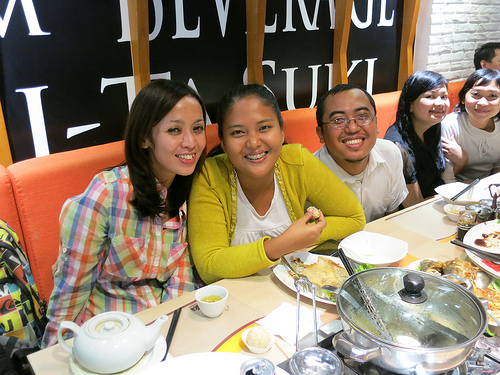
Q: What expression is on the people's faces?
A: Smile.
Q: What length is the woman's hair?
A: Mid length.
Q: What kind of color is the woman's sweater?
A: Yellow.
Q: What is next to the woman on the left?
A: Tea kettle.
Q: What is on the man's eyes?
A: Glasses.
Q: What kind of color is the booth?
A: Orange.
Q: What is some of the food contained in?
A: Pot.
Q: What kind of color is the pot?
A: Silver.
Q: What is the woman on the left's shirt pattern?
A: Checkered plaid.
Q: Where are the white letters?
A: Behind the chair.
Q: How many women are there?
A: 4.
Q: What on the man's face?
A: Glasses.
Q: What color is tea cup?
A: White.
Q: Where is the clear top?
A: On the silver pot.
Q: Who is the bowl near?
A: Middle woman.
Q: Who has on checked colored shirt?
A: Girl on left.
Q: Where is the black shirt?
A: On right.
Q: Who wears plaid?
A: The girl on the left.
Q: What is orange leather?
A: The bench.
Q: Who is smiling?
A: All the people.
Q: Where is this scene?
A: A restaurant.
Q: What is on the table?
A: Dishes of food.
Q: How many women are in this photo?
A: 4.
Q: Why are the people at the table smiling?
A: For the photo.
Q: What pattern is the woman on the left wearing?
A: Plaid.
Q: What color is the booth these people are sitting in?
A: Orange.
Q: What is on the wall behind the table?
A: Letters.